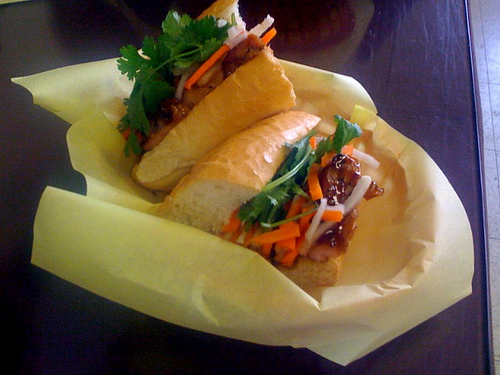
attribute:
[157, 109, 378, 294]
sandwich — food, half, cut, sliced, meal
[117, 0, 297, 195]
sandwich — food, half, cut, sliced, meal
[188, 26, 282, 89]
carrots — orange, sliced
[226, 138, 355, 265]
carrots — orange, sliced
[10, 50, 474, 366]
paper — white, yellow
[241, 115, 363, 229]
greens — parsley, green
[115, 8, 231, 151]
greens — parsley, green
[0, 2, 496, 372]
table — blue, dark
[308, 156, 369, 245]
meat — oily, moist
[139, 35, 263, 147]
meat — oily, moist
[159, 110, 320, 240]
bread — brown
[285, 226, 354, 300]
bread — brown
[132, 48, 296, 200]
bread — brown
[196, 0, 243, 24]
bread — brown